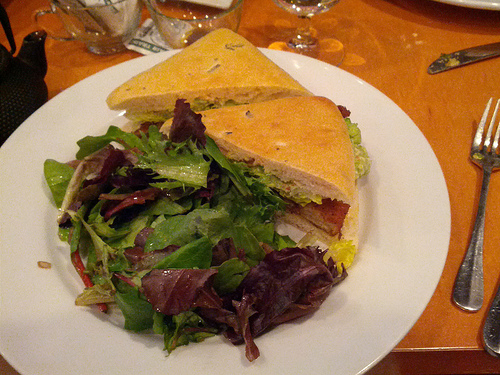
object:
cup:
[34, 0, 141, 51]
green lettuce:
[154, 235, 212, 268]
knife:
[427, 41, 499, 75]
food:
[37, 26, 370, 366]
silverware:
[451, 98, 498, 355]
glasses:
[151, 1, 348, 54]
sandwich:
[105, 26, 356, 244]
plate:
[4, 47, 449, 368]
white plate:
[0, 47, 451, 375]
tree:
[437, 88, 497, 321]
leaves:
[43, 98, 370, 362]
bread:
[106, 28, 355, 206]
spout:
[0, 31, 87, 116]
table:
[2, 0, 499, 353]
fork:
[450, 96, 500, 313]